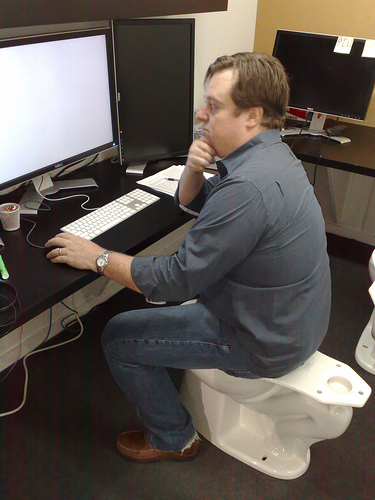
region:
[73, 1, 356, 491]
Man sitting in front of a desk.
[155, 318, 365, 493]
White toilet as a computer seat.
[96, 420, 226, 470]
Brown shoe on the man's foot.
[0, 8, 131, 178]
Large computer monitor turned on.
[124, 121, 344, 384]
Blue shirt on the man.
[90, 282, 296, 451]
The man is wearing jeans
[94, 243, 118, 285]
Watch on the man's wrist.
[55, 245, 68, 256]
Wedding ring on the man's hand.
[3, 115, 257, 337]
The desktop is black.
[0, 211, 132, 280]
The man is left-handed.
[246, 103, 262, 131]
an ear of a person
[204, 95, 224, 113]
an eye of a person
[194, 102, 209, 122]
a nose of a person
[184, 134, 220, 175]
a hand resting on a chin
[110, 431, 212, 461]
a brown shoe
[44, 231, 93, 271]
a hand of a person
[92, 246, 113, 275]
a watch on a wrist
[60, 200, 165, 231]
a computer keyboard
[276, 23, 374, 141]
a computer moniter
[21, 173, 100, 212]
the base of a computer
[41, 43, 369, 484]
a man sitting on a porcelain toilet bowl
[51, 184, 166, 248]
an Apple extended keyboard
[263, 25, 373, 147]
a switched off computer monitor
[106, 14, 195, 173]
a switched off computer monitor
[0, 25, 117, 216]
a widescreen computer monitor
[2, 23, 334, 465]
a man using a desktop computer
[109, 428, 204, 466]
a brown loafer shoe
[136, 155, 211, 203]
a stack of paperwork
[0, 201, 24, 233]
a small metal container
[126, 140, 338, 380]
a dark blue long sleeve shirt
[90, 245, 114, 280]
a man's silver watch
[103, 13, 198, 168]
a computer monitor in portrait mode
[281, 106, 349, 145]
a computer monitor stand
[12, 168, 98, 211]
a computer monitor stand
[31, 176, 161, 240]
a wired computer keyboard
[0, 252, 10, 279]
a green felt marker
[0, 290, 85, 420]
a grey electric wire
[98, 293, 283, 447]
a pair of men's blue jeans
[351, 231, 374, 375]
a white porcelain toilet bowl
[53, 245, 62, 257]
a man's wedding ring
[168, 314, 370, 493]
A toilet.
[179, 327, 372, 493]
The toilet is white.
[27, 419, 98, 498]
The floor is dark gray.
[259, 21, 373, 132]
A computer monitor.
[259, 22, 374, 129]
The computer monitor is off.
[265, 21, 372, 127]
The monitor has notes on it.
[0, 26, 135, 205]
The monitor is large.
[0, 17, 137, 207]
The monitor is on.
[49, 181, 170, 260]
The keyboard is white.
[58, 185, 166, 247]
The keyboard is thin.